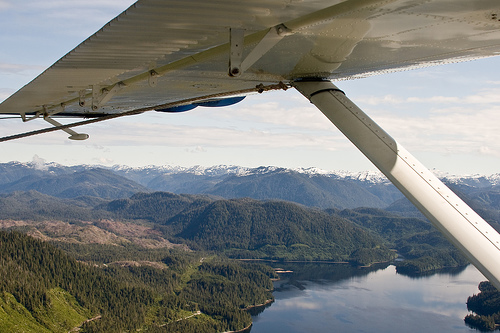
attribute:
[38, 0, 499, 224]
plane — white, flying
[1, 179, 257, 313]
mountains — green, tall, big, huge, large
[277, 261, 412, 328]
water — blue, clear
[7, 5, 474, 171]
sky — white, clear